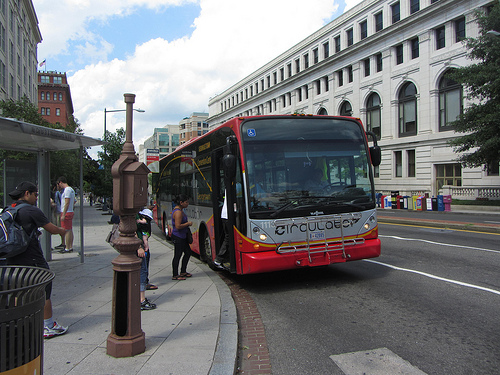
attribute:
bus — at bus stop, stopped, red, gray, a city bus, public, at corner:
[144, 111, 386, 278]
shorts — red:
[58, 210, 76, 230]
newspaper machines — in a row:
[376, 187, 457, 214]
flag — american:
[37, 54, 47, 69]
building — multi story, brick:
[34, 68, 75, 131]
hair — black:
[171, 191, 186, 206]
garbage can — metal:
[0, 263, 59, 375]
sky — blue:
[35, 3, 350, 150]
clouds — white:
[83, 17, 262, 103]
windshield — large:
[237, 115, 376, 214]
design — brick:
[232, 277, 274, 374]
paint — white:
[370, 231, 498, 294]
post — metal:
[77, 145, 86, 259]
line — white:
[364, 229, 499, 295]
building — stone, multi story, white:
[205, 1, 499, 208]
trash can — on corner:
[2, 263, 56, 372]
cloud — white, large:
[67, 2, 313, 114]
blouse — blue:
[168, 207, 194, 240]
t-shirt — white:
[59, 184, 76, 216]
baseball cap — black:
[10, 178, 38, 203]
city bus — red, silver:
[149, 110, 384, 279]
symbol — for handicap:
[244, 124, 258, 140]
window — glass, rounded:
[361, 90, 386, 143]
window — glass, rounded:
[390, 75, 419, 141]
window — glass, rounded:
[430, 60, 472, 136]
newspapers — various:
[375, 186, 453, 214]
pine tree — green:
[447, 5, 500, 173]